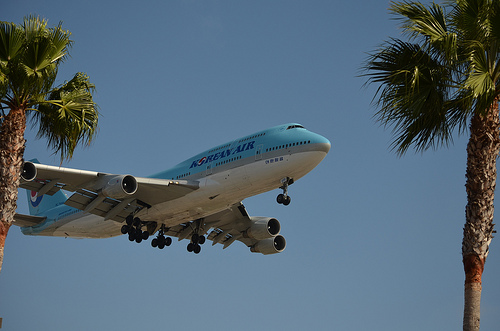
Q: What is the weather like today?
A: It is clear.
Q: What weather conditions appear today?
A: It is clear.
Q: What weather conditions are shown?
A: It is clear.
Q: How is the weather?
A: It is clear.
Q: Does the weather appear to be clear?
A: Yes, it is clear.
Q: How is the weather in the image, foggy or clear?
A: It is clear.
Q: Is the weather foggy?
A: No, it is clear.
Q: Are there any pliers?
A: No, there are no pliers.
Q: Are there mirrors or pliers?
A: No, there are no pliers or mirrors.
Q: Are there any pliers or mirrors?
A: No, there are no pliers or mirrors.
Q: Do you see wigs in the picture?
A: No, there are no wigs.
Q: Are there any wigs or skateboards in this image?
A: No, there are no wigs or skateboards.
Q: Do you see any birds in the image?
A: No, there are no birds.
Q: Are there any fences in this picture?
A: No, there are no fences.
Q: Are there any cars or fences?
A: No, there are no fences or cars.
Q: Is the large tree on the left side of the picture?
A: Yes, the palm tree is on the left of the image.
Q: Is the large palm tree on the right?
A: No, the palm tree is on the left of the image.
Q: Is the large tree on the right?
A: No, the palm tree is on the left of the image.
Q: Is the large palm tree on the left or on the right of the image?
A: The palm tree is on the left of the image.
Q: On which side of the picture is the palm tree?
A: The palm tree is on the left of the image.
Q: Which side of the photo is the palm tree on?
A: The palm tree is on the left of the image.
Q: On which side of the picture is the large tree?
A: The palm tree is on the left of the image.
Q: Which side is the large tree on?
A: The palm tree is on the left of the image.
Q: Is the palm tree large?
A: Yes, the palm tree is large.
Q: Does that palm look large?
A: Yes, the palm is large.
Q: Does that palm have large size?
A: Yes, the palm is large.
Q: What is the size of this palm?
A: The palm is large.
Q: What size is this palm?
A: The palm is large.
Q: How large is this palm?
A: The palm is large.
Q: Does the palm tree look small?
A: No, the palm tree is large.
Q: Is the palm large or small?
A: The palm is large.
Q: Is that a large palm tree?
A: Yes, that is a large palm tree.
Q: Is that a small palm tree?
A: No, that is a large palm tree.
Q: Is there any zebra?
A: No, there are no zebras.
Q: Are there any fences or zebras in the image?
A: No, there are no zebras or fences.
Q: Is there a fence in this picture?
A: No, there are no fences.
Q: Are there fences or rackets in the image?
A: No, there are no fences or rackets.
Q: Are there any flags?
A: No, there are no flags.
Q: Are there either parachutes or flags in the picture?
A: No, there are no flags or parachutes.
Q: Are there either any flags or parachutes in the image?
A: No, there are no flags or parachutes.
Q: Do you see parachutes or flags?
A: No, there are no flags or parachutes.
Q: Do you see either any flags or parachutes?
A: No, there are no flags or parachutes.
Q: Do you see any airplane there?
A: Yes, there is an airplane.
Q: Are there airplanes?
A: Yes, there is an airplane.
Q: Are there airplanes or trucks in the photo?
A: Yes, there is an airplane.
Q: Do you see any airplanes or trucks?
A: Yes, there is an airplane.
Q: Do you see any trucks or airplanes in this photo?
A: Yes, there is an airplane.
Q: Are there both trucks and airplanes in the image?
A: No, there is an airplane but no trucks.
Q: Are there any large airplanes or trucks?
A: Yes, there is a large airplane.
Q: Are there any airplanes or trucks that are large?
A: Yes, the airplane is large.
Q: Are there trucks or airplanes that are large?
A: Yes, the airplane is large.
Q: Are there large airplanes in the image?
A: Yes, there is a large airplane.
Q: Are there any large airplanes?
A: Yes, there is a large airplane.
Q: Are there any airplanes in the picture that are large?
A: Yes, there is an airplane that is large.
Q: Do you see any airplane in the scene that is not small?
A: Yes, there is a large airplane.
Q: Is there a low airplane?
A: Yes, there is a low airplane.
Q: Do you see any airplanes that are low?
A: Yes, there is an airplane that is low.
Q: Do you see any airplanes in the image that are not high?
A: Yes, there is a low airplane.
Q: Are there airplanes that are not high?
A: Yes, there is a low airplane.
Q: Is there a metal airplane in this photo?
A: Yes, there is a metal airplane.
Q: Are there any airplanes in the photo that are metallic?
A: Yes, there is an airplane that is metallic.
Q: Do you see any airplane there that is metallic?
A: Yes, there is an airplane that is metallic.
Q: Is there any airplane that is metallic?
A: Yes, there is an airplane that is metallic.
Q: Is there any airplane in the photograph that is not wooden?
A: Yes, there is a metallic airplane.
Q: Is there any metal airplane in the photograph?
A: Yes, there is an airplane that is made of metal.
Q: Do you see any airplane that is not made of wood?
A: Yes, there is an airplane that is made of metal.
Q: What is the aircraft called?
A: The aircraft is an airplane.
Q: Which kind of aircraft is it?
A: The aircraft is an airplane.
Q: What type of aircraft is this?
A: This is an airplane.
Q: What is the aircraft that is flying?
A: The aircraft is an airplane.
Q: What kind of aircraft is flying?
A: The aircraft is an airplane.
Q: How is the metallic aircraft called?
A: The aircraft is an airplane.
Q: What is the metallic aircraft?
A: The aircraft is an airplane.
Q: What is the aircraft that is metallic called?
A: The aircraft is an airplane.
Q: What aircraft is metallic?
A: The aircraft is an airplane.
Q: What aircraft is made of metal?
A: The aircraft is an airplane.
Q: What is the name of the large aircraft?
A: The aircraft is an airplane.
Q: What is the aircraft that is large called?
A: The aircraft is an airplane.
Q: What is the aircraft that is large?
A: The aircraft is an airplane.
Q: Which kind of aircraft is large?
A: The aircraft is an airplane.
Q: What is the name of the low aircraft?
A: The aircraft is an airplane.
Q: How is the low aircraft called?
A: The aircraft is an airplane.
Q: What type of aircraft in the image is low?
A: The aircraft is an airplane.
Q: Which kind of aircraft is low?
A: The aircraft is an airplane.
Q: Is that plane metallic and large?
A: Yes, the plane is metallic and large.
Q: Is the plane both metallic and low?
A: Yes, the plane is metallic and low.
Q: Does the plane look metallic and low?
A: Yes, the plane is metallic and low.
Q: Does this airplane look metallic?
A: Yes, the airplane is metallic.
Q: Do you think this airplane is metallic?
A: Yes, the airplane is metallic.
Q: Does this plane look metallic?
A: Yes, the plane is metallic.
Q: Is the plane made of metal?
A: Yes, the plane is made of metal.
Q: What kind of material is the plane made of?
A: The plane is made of metal.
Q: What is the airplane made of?
A: The plane is made of metal.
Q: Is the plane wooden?
A: No, the plane is metallic.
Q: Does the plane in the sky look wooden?
A: No, the plane is metallic.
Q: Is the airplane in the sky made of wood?
A: No, the plane is made of metal.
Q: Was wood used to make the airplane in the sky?
A: No, the plane is made of metal.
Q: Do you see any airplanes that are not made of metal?
A: No, there is an airplane but it is made of metal.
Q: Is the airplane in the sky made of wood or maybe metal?
A: The plane is made of metal.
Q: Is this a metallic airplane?
A: Yes, this is a metallic airplane.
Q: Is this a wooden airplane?
A: No, this is a metallic airplane.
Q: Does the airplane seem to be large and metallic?
A: Yes, the airplane is large and metallic.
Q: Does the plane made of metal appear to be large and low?
A: Yes, the airplane is large and low.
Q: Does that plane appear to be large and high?
A: No, the plane is large but low.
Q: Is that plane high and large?
A: No, the plane is large but low.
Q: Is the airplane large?
A: Yes, the airplane is large.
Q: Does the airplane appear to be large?
A: Yes, the airplane is large.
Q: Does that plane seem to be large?
A: Yes, the plane is large.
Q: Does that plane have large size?
A: Yes, the plane is large.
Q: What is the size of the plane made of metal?
A: The airplane is large.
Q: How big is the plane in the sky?
A: The airplane is large.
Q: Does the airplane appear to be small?
A: No, the airplane is large.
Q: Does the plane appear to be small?
A: No, the plane is large.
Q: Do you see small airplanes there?
A: No, there is an airplane but it is large.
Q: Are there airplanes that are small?
A: No, there is an airplane but it is large.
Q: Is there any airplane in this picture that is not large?
A: No, there is an airplane but it is large.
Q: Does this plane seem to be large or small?
A: The plane is large.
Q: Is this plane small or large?
A: The plane is large.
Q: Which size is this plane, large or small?
A: The plane is large.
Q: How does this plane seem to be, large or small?
A: The plane is large.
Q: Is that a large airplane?
A: Yes, that is a large airplane.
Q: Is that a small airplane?
A: No, that is a large airplane.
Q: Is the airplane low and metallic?
A: Yes, the airplane is low and metallic.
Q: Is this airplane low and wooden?
A: No, the airplane is low but metallic.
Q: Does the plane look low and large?
A: Yes, the plane is low and large.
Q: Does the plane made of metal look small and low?
A: No, the airplane is low but large.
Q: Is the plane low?
A: Yes, the plane is low.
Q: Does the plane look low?
A: Yes, the plane is low.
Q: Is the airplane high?
A: No, the airplane is low.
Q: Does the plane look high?
A: No, the plane is low.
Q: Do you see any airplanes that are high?
A: No, there is an airplane but it is low.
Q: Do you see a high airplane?
A: No, there is an airplane but it is low.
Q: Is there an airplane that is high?
A: No, there is an airplane but it is low.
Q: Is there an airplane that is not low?
A: No, there is an airplane but it is low.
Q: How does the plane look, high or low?
A: The plane is low.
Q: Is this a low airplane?
A: Yes, this is a low airplane.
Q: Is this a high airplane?
A: No, this is a low airplane.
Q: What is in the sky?
A: The plane is in the sky.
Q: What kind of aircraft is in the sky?
A: The aircraft is an airplane.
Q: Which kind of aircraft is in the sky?
A: The aircraft is an airplane.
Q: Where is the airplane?
A: The airplane is in the sky.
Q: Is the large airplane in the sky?
A: Yes, the airplane is in the sky.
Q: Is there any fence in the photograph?
A: No, there are no fences.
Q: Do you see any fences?
A: No, there are no fences.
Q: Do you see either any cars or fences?
A: No, there are no fences or cars.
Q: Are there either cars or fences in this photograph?
A: No, there are no fences or cars.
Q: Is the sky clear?
A: Yes, the sky is clear.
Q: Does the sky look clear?
A: Yes, the sky is clear.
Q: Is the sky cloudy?
A: No, the sky is clear.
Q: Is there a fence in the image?
A: No, there are no fences.